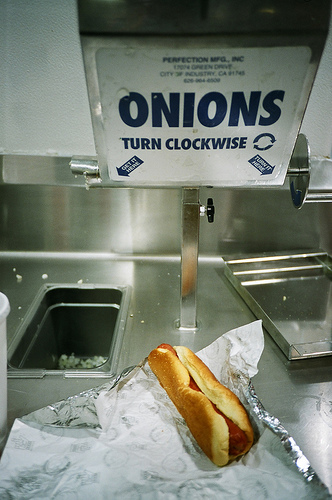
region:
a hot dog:
[135, 320, 274, 473]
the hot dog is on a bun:
[150, 335, 256, 494]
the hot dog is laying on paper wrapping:
[108, 343, 270, 497]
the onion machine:
[41, 37, 322, 231]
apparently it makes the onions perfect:
[73, 44, 316, 204]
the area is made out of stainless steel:
[20, 203, 159, 275]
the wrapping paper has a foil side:
[40, 400, 121, 440]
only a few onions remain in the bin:
[41, 332, 109, 376]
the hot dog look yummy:
[138, 334, 256, 493]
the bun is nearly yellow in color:
[143, 339, 269, 499]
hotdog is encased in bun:
[143, 336, 261, 463]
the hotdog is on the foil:
[151, 347, 255, 457]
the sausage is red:
[160, 341, 244, 444]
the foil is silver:
[61, 402, 103, 428]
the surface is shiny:
[124, 245, 180, 308]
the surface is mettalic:
[138, 296, 175, 330]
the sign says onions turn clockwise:
[122, 95, 267, 158]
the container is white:
[1, 293, 22, 422]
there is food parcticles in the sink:
[54, 348, 110, 374]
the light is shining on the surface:
[301, 400, 330, 454]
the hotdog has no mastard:
[165, 351, 248, 447]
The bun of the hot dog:
[149, 342, 258, 466]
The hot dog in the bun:
[160, 343, 250, 453]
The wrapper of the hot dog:
[0, 318, 331, 498]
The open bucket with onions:
[6, 280, 124, 381]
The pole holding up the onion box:
[175, 190, 214, 333]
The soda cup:
[0, 292, 18, 442]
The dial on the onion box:
[290, 135, 314, 211]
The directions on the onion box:
[119, 130, 275, 153]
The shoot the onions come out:
[67, 157, 104, 193]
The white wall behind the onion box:
[1, 0, 331, 161]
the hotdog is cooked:
[132, 310, 268, 467]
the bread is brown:
[139, 322, 234, 469]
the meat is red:
[158, 325, 259, 464]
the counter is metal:
[14, 243, 147, 415]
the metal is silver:
[107, 231, 177, 354]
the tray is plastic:
[18, 265, 130, 390]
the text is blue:
[112, 73, 290, 143]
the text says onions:
[105, 70, 283, 139]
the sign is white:
[90, 34, 307, 186]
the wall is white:
[17, 29, 74, 128]